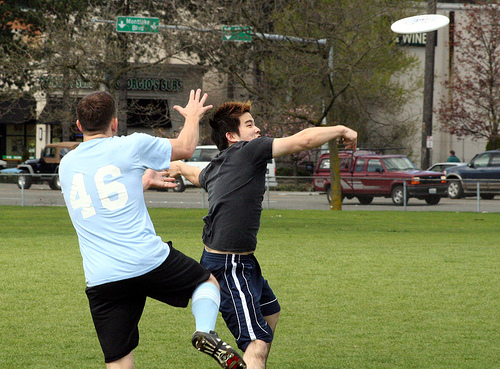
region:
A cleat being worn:
[190, 329, 244, 367]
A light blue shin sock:
[190, 282, 220, 332]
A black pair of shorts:
[83, 244, 210, 362]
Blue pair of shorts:
[200, 251, 279, 347]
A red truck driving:
[314, 152, 446, 206]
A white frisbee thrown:
[392, 13, 448, 34]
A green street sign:
[115, 18, 160, 31]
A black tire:
[15, 172, 30, 187]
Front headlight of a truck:
[410, 176, 419, 184]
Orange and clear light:
[439, 175, 446, 184]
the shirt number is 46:
[45, 128, 158, 256]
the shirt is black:
[184, 130, 296, 296]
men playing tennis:
[46, 68, 386, 361]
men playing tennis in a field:
[69, 30, 448, 365]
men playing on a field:
[54, 75, 325, 361]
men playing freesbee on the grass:
[74, 39, 406, 364]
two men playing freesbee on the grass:
[69, 58, 438, 365]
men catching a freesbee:
[47, 9, 497, 317]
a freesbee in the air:
[359, 7, 493, 85]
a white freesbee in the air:
[390, 2, 454, 65]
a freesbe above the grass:
[347, 15, 475, 58]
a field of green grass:
[25, 183, 378, 363]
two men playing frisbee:
[65, 62, 361, 356]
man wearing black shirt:
[175, 101, 301, 343]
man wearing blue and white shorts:
[192, 98, 307, 335]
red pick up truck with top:
[316, 135, 449, 211]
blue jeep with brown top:
[17, 130, 85, 190]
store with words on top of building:
[30, 56, 230, 159]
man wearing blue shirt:
[53, 93, 222, 338]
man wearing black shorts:
[46, 93, 221, 349]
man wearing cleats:
[59, 90, 238, 356]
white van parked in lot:
[167, 138, 270, 186]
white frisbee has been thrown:
[391, 12, 451, 48]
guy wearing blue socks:
[183, 276, 250, 365]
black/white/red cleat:
[184, 330, 251, 363]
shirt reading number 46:
[75, 143, 132, 218]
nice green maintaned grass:
[319, 226, 446, 346]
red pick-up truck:
[317, 150, 466, 217]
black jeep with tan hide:
[26, 145, 88, 189]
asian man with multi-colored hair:
[207, 92, 269, 147]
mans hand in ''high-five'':
[163, 93, 219, 123]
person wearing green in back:
[448, 144, 477, 176]